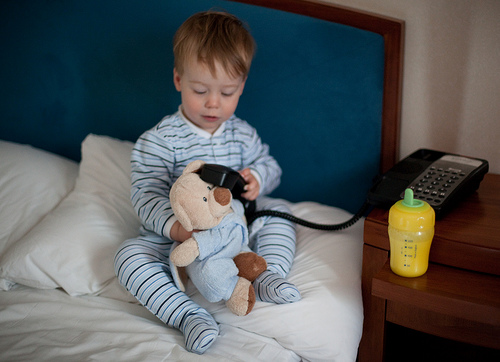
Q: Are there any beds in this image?
A: Yes, there is a bed.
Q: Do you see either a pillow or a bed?
A: Yes, there is a bed.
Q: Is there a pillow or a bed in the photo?
A: Yes, there is a bed.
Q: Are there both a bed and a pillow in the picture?
A: Yes, there are both a bed and a pillow.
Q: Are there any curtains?
A: No, there are no curtains.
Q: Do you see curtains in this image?
A: No, there are no curtains.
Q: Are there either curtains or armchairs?
A: No, there are no curtains or armchairs.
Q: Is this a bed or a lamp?
A: This is a bed.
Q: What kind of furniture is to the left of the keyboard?
A: The piece of furniture is a bed.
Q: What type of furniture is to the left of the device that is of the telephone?
A: The piece of furniture is a bed.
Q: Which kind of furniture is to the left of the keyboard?
A: The piece of furniture is a bed.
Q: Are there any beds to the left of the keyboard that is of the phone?
A: Yes, there is a bed to the left of the keyboard.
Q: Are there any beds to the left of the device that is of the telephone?
A: Yes, there is a bed to the left of the keyboard.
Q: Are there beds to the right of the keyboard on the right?
A: No, the bed is to the left of the keyboard.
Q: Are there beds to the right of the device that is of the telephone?
A: No, the bed is to the left of the keyboard.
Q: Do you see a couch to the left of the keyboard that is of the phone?
A: No, there is a bed to the left of the keyboard.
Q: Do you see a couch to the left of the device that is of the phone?
A: No, there is a bed to the left of the keyboard.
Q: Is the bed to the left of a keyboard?
A: Yes, the bed is to the left of a keyboard.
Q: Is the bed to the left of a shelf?
A: No, the bed is to the left of a keyboard.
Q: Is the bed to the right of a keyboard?
A: No, the bed is to the left of a keyboard.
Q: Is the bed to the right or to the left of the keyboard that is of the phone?
A: The bed is to the left of the keyboard.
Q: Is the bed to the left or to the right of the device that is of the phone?
A: The bed is to the left of the keyboard.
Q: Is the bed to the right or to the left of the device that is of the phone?
A: The bed is to the left of the keyboard.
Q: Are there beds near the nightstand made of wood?
A: Yes, there is a bed near the nightstand.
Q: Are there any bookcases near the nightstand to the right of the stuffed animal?
A: No, there is a bed near the nightstand.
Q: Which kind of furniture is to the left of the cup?
A: The piece of furniture is a bed.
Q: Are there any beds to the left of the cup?
A: Yes, there is a bed to the left of the cup.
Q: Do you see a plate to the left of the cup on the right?
A: No, there is a bed to the left of the cup.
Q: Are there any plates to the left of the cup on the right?
A: No, there is a bed to the left of the cup.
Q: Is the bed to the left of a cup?
A: Yes, the bed is to the left of a cup.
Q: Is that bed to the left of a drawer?
A: No, the bed is to the left of a cup.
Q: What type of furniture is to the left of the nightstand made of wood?
A: The piece of furniture is a bed.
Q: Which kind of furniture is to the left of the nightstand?
A: The piece of furniture is a bed.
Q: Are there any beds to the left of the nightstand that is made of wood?
A: Yes, there is a bed to the left of the nightstand.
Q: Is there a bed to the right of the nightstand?
A: No, the bed is to the left of the nightstand.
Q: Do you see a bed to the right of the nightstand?
A: No, the bed is to the left of the nightstand.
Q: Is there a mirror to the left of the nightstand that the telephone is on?
A: No, there is a bed to the left of the nightstand.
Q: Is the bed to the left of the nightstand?
A: Yes, the bed is to the left of the nightstand.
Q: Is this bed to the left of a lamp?
A: No, the bed is to the left of the nightstand.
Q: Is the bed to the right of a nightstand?
A: No, the bed is to the left of a nightstand.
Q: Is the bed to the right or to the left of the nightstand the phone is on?
A: The bed is to the left of the nightstand.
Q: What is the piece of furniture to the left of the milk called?
A: The piece of furniture is a bed.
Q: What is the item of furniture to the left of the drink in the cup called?
A: The piece of furniture is a bed.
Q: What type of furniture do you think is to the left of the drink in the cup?
A: The piece of furniture is a bed.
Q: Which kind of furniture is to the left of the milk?
A: The piece of furniture is a bed.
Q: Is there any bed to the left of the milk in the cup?
A: Yes, there is a bed to the left of the milk.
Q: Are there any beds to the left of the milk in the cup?
A: Yes, there is a bed to the left of the milk.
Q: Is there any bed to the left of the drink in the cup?
A: Yes, there is a bed to the left of the milk.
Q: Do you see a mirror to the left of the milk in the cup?
A: No, there is a bed to the left of the milk.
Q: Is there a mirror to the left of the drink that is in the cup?
A: No, there is a bed to the left of the milk.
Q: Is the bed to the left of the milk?
A: Yes, the bed is to the left of the milk.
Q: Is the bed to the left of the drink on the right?
A: Yes, the bed is to the left of the milk.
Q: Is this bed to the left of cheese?
A: No, the bed is to the left of the milk.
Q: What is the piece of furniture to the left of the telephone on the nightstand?
A: The piece of furniture is a bed.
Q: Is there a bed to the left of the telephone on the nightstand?
A: Yes, there is a bed to the left of the phone.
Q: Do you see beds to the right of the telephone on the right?
A: No, the bed is to the left of the telephone.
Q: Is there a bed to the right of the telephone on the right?
A: No, the bed is to the left of the telephone.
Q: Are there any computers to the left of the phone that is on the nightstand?
A: No, there is a bed to the left of the phone.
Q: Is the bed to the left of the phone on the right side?
A: Yes, the bed is to the left of the telephone.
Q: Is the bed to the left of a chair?
A: No, the bed is to the left of the telephone.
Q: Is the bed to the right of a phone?
A: No, the bed is to the left of a phone.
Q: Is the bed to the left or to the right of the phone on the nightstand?
A: The bed is to the left of the phone.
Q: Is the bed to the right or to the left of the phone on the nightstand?
A: The bed is to the left of the phone.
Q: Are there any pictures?
A: No, there are no pictures.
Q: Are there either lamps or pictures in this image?
A: No, there are no pictures or lamps.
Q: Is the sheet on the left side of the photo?
A: Yes, the sheet is on the left of the image.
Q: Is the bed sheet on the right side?
A: No, the bed sheet is on the left of the image.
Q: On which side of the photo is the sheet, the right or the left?
A: The sheet is on the left of the image.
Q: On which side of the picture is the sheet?
A: The sheet is on the left of the image.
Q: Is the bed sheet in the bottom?
A: Yes, the bed sheet is in the bottom of the image.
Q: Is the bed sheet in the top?
A: No, the bed sheet is in the bottom of the image.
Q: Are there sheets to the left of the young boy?
A: Yes, there is a sheet to the left of the boy.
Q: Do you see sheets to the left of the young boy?
A: Yes, there is a sheet to the left of the boy.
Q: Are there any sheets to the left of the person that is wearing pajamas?
A: Yes, there is a sheet to the left of the boy.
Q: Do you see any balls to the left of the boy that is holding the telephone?
A: No, there is a sheet to the left of the boy.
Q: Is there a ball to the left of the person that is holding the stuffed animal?
A: No, there is a sheet to the left of the boy.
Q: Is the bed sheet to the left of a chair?
A: No, the bed sheet is to the left of the boy.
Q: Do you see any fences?
A: No, there are no fences.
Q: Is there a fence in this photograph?
A: No, there are no fences.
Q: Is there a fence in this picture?
A: No, there are no fences.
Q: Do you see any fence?
A: No, there are no fences.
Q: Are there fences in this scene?
A: No, there are no fences.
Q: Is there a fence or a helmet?
A: No, there are no fences or helmets.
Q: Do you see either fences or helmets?
A: No, there are no fences or helmets.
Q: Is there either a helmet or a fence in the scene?
A: No, there are no fences or helmets.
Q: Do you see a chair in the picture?
A: No, there are no chairs.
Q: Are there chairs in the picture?
A: No, there are no chairs.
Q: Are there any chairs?
A: No, there are no chairs.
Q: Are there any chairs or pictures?
A: No, there are no chairs or pictures.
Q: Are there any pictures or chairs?
A: No, there are no chairs or pictures.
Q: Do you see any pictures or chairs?
A: No, there are no chairs or pictures.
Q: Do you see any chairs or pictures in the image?
A: No, there are no chairs or pictures.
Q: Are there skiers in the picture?
A: No, there are no skiers.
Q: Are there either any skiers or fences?
A: No, there are no skiers or fences.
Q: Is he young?
A: Yes, the boy is young.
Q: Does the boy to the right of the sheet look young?
A: Yes, the boy is young.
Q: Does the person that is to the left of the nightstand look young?
A: Yes, the boy is young.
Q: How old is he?
A: The boy is young.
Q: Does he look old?
A: No, the boy is young.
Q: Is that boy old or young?
A: The boy is young.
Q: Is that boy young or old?
A: The boy is young.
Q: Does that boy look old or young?
A: The boy is young.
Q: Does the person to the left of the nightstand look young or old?
A: The boy is young.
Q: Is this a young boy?
A: Yes, this is a young boy.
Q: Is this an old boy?
A: No, this is a young boy.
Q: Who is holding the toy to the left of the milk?
A: The boy is holding the stuffed animal.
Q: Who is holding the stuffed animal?
A: The boy is holding the stuffed animal.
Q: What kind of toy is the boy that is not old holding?
A: The boy is holding the stuffed animal.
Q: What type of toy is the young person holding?
A: The boy is holding the stuffed animal.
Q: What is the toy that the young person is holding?
A: The toy is a stuffed animal.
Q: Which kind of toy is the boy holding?
A: The boy is holding the stuffed animal.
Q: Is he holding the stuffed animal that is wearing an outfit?
A: Yes, the boy is holding the stuffed animal.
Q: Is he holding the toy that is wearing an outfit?
A: Yes, the boy is holding the stuffed animal.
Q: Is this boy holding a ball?
A: No, the boy is holding the stuffed animal.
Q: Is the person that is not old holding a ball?
A: No, the boy is holding the stuffed animal.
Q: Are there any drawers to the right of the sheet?
A: No, there is a boy to the right of the sheet.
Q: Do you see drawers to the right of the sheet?
A: No, there is a boy to the right of the sheet.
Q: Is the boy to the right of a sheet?
A: Yes, the boy is to the right of a sheet.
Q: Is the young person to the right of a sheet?
A: Yes, the boy is to the right of a sheet.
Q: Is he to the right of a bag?
A: No, the boy is to the right of a sheet.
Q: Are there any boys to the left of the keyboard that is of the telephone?
A: Yes, there is a boy to the left of the keyboard.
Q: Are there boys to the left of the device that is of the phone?
A: Yes, there is a boy to the left of the keyboard.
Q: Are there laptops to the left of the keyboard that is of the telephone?
A: No, there is a boy to the left of the keyboard.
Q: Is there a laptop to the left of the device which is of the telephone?
A: No, there is a boy to the left of the keyboard.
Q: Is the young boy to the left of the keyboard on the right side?
A: Yes, the boy is to the left of the keyboard.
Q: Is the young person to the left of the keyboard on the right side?
A: Yes, the boy is to the left of the keyboard.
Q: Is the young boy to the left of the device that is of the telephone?
A: Yes, the boy is to the left of the keyboard.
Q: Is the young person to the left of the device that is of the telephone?
A: Yes, the boy is to the left of the keyboard.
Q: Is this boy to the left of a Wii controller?
A: No, the boy is to the left of the keyboard.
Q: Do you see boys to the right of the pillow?
A: Yes, there is a boy to the right of the pillow.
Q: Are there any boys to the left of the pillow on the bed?
A: No, the boy is to the right of the pillow.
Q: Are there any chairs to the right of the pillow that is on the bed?
A: No, there is a boy to the right of the pillow.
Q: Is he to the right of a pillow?
A: Yes, the boy is to the right of a pillow.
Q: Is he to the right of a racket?
A: No, the boy is to the right of a pillow.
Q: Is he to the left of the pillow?
A: No, the boy is to the right of the pillow.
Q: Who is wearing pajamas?
A: The boy is wearing pajamas.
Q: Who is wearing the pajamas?
A: The boy is wearing pajamas.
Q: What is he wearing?
A: The boy is wearing pajamas.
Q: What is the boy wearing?
A: The boy is wearing pajamas.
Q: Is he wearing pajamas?
A: Yes, the boy is wearing pajamas.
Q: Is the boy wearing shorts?
A: No, the boy is wearing pajamas.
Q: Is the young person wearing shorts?
A: No, the boy is wearing pajamas.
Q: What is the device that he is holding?
A: The device is a phone.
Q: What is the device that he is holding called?
A: The device is a phone.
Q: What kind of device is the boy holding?
A: The boy is holding the telephone.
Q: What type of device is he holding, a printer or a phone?
A: The boy is holding a phone.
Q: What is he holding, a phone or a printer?
A: The boy is holding a phone.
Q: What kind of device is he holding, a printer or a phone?
A: The boy is holding a phone.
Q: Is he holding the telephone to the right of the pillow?
A: Yes, the boy is holding the phone.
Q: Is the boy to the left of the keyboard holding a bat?
A: No, the boy is holding the phone.